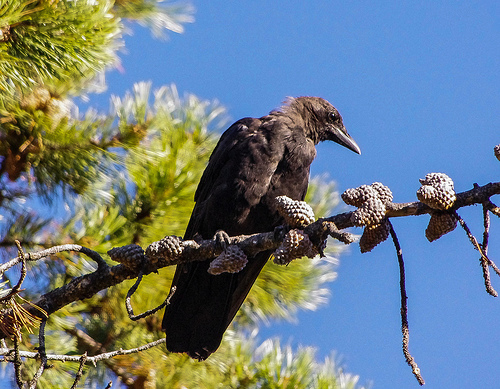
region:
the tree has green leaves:
[240, 349, 260, 382]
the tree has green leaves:
[277, 345, 288, 387]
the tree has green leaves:
[264, 357, 278, 387]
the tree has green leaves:
[273, 359, 293, 386]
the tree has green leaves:
[283, 381, 285, 382]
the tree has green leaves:
[257, 359, 273, 386]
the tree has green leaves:
[269, 360, 283, 383]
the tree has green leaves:
[260, 377, 270, 387]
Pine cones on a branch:
[335, 168, 472, 275]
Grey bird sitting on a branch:
[189, 83, 352, 350]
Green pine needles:
[12, 4, 122, 84]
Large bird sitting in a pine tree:
[14, 4, 406, 387]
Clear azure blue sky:
[355, 5, 491, 125]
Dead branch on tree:
[7, 326, 152, 386]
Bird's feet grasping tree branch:
[200, 222, 235, 262]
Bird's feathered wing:
[175, 116, 271, 226]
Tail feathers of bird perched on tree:
[160, 241, 251, 358]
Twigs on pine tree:
[376, 205, 493, 385]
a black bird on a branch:
[156, 90, 369, 371]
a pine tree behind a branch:
[3, 0, 364, 385]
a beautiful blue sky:
[9, 1, 496, 387]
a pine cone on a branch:
[414, 184, 460, 210]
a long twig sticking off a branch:
[383, 221, 432, 385]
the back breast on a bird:
[252, 130, 307, 226]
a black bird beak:
[328, 125, 361, 153]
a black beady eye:
[326, 110, 339, 121]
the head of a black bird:
[285, 91, 369, 153]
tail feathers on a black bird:
[162, 262, 236, 357]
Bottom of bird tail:
[160, 283, 232, 360]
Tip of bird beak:
[341, 134, 366, 158]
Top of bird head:
[292, 92, 328, 110]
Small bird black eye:
[322, 104, 347, 126]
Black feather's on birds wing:
[202, 117, 259, 229]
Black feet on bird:
[204, 223, 237, 256]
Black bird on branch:
[148, 79, 365, 357]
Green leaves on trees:
[121, 86, 196, 205]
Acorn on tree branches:
[203, 246, 251, 286]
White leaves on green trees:
[315, 258, 337, 315]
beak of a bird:
[351, 138, 356, 146]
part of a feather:
[201, 297, 208, 314]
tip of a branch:
[65, 307, 78, 327]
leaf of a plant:
[141, 190, 147, 195]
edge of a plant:
[62, 146, 72, 153]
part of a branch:
[62, 275, 69, 285]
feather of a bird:
[357, 280, 387, 316]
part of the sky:
[328, 290, 373, 307]